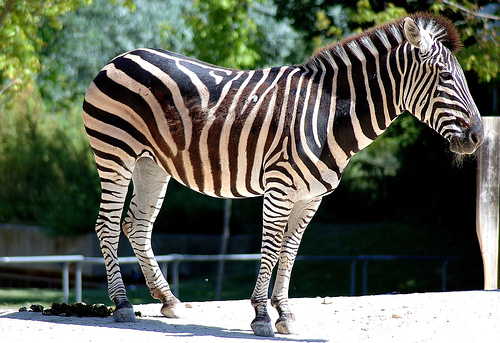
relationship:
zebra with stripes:
[70, 7, 484, 335] [202, 79, 291, 186]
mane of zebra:
[308, 17, 454, 78] [70, 7, 484, 335]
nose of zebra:
[468, 122, 489, 149] [70, 7, 484, 335]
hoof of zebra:
[271, 310, 302, 337] [70, 7, 484, 335]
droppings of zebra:
[27, 295, 113, 320] [70, 7, 484, 335]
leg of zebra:
[244, 137, 320, 341] [70, 7, 484, 335]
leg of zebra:
[266, 182, 335, 341] [70, 7, 484, 335]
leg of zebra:
[79, 101, 144, 318] [70, 7, 484, 335]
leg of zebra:
[119, 161, 191, 322] [70, 7, 484, 335]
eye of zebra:
[435, 69, 460, 88] [70, 7, 484, 335]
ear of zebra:
[397, 13, 430, 56] [70, 7, 484, 335]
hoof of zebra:
[248, 310, 276, 342] [70, 7, 484, 335]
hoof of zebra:
[107, 302, 140, 329] [70, 7, 484, 335]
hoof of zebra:
[153, 298, 190, 323] [70, 7, 484, 335]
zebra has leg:
[70, 7, 484, 335] [244, 137, 320, 341]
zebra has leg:
[70, 7, 484, 335] [266, 182, 335, 341]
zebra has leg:
[70, 7, 484, 335] [79, 101, 144, 318]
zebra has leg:
[70, 7, 484, 335] [119, 161, 191, 322]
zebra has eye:
[70, 7, 484, 335] [435, 69, 460, 88]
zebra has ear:
[70, 7, 484, 335] [397, 13, 430, 56]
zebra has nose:
[70, 7, 484, 335] [468, 122, 489, 149]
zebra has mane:
[70, 7, 484, 335] [308, 17, 454, 78]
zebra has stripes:
[70, 7, 484, 335] [202, 79, 291, 186]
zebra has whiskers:
[70, 7, 484, 335] [455, 152, 468, 166]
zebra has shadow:
[70, 7, 484, 335] [18, 312, 298, 342]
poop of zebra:
[27, 295, 113, 320] [70, 7, 484, 335]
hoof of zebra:
[250, 315, 274, 338] [70, 7, 484, 335]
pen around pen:
[0, 251, 482, 307] [7, 236, 499, 334]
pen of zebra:
[7, 236, 499, 334] [70, 7, 484, 335]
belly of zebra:
[146, 142, 270, 197] [70, 7, 484, 335]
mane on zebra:
[308, 17, 454, 78] [70, 7, 484, 335]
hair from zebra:
[455, 152, 468, 166] [70, 7, 484, 335]